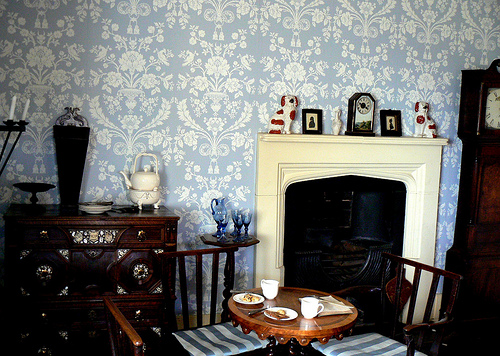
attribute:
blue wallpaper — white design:
[71, 44, 240, 99]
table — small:
[166, 217, 263, 341]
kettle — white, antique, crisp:
[118, 150, 165, 212]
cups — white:
[255, 276, 323, 325]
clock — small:
[342, 85, 374, 136]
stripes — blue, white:
[308, 333, 420, 354]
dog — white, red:
[268, 95, 300, 132]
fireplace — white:
[256, 133, 448, 324]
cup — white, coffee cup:
[302, 295, 323, 319]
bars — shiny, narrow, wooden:
[304, 256, 466, 354]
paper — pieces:
[251, 250, 351, 350]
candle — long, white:
[21, 98, 31, 122]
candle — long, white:
[9, 95, 17, 122]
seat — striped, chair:
[313, 329, 410, 354]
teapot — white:
[117, 150, 164, 210]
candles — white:
[8, 95, 31, 120]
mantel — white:
[252, 131, 449, 323]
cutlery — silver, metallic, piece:
[241, 307, 263, 319]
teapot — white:
[118, 148, 170, 210]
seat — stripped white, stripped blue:
[349, 338, 400, 353]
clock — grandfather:
[465, 52, 496, 132]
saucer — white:
[261, 304, 296, 324]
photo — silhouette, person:
[293, 103, 331, 143]